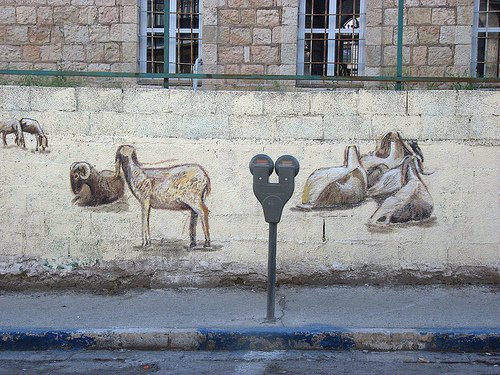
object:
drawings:
[0, 117, 50, 151]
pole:
[266, 224, 278, 321]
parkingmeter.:
[249, 153, 302, 319]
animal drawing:
[113, 144, 212, 250]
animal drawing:
[69, 160, 126, 206]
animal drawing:
[0, 117, 49, 152]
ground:
[432, 162, 499, 223]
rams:
[0, 118, 436, 251]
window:
[295, 0, 366, 85]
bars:
[297, 0, 366, 80]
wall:
[0, 0, 499, 293]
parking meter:
[248, 154, 300, 324]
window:
[140, 0, 204, 86]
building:
[0, 0, 499, 288]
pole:
[396, 0, 408, 91]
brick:
[27, 26, 52, 45]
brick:
[40, 44, 62, 62]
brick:
[52, 5, 80, 25]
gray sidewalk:
[0, 283, 499, 333]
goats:
[295, 129, 439, 225]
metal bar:
[139, 0, 202, 73]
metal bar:
[296, 1, 364, 78]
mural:
[0, 85, 499, 290]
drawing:
[301, 130, 435, 226]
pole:
[0, 68, 499, 84]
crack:
[276, 293, 296, 329]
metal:
[294, 0, 363, 84]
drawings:
[68, 161, 127, 206]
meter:
[248, 153, 300, 322]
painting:
[198, 323, 360, 356]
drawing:
[112, 144, 211, 252]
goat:
[112, 144, 212, 249]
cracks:
[95, 291, 262, 326]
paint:
[0, 322, 499, 356]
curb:
[0, 325, 500, 354]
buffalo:
[69, 161, 125, 207]